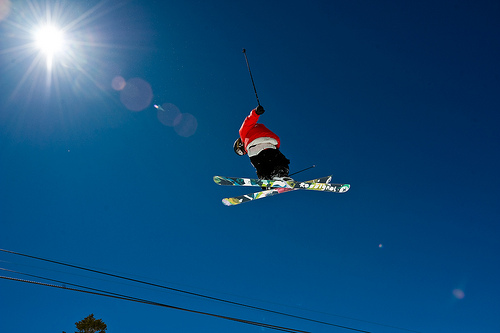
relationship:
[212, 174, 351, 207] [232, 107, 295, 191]
skis under person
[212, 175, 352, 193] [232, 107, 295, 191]
ski under person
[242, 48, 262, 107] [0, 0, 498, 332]
ski pole in air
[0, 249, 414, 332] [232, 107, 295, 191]
power lines under person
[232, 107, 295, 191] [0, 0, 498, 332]
person in air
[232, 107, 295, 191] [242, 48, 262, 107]
person holding ski pole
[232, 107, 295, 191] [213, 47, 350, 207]
person doing tricks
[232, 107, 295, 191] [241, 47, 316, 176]
person holding ski poles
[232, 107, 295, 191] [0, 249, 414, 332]
person above power lines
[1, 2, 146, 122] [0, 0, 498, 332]
sun in sky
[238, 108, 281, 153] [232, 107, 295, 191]
jacket on person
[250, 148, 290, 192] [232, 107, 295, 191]
pants on person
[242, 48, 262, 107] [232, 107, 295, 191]
ski pole held by person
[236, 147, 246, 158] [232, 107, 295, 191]
goggles on person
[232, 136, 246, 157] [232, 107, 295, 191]
helmet on person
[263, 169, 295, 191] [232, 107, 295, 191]
ski boots on person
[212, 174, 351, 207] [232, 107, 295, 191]
skis worn by person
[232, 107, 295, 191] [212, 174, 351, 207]
person wearing skis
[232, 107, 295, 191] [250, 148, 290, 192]
person wearing pants